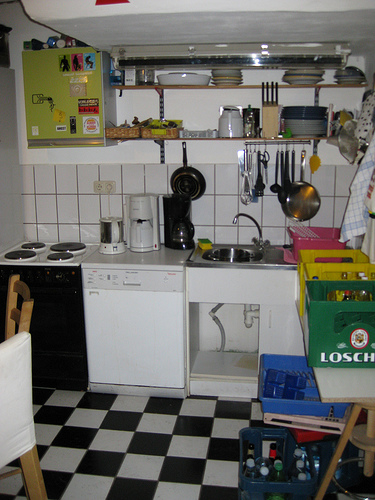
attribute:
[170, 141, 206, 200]
frying pan — metal, black, hanging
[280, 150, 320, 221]
pot — metal, silver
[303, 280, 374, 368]
crate — plastic, green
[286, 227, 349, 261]
dish rack — pink, red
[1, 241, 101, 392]
stove — small, black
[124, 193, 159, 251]
coffee pot — white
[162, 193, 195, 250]
coffee pot — black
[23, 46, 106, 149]
cabinet door — green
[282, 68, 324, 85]
bowls — stacked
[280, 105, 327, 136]
plates — stacked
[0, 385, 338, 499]
floor — white, black, checkered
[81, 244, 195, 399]
dishwasher — white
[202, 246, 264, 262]
sink — small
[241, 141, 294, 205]
utensils — hanging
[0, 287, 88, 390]
oven — small, black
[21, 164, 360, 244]
backsplash — tiled, white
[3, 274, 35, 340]
chair — wooden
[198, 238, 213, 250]
sponge — yellow, green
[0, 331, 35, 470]
back — white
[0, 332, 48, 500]
chair — wooden